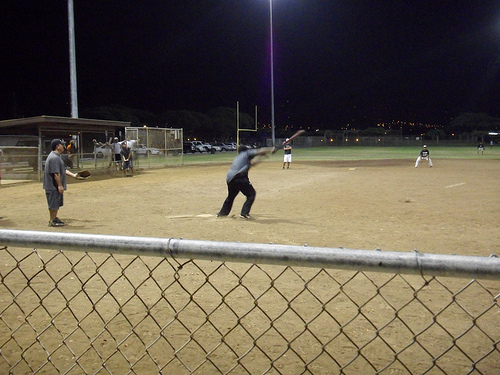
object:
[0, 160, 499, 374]
field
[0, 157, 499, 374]
dirt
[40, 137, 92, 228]
players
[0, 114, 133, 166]
dugout